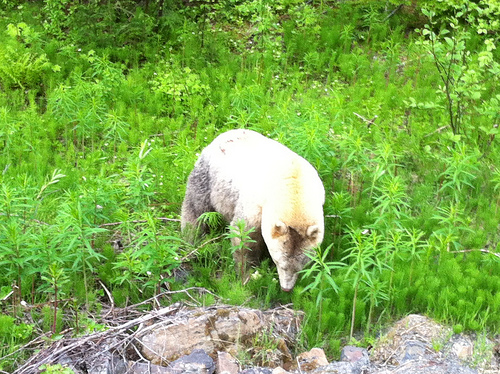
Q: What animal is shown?
A: Bear.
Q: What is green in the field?
A: Vegetation.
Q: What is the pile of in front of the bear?
A: Rocks.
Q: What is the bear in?
A: Grass.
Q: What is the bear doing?
A: Standing.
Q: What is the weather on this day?
A: Sunny.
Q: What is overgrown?
A: Plants.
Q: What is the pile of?
A: A pile of rocks.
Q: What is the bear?
A: A lightly colored bear.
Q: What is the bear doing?
A: A bear looking for food.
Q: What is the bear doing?
A: A bear foraging for food.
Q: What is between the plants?
A: A bear between plants.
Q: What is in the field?
A: A field of various plants.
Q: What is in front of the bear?
A: Rocks and stones in front of bear.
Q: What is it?
A: A bear.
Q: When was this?
A: Daytime.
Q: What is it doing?
A: Looking for food.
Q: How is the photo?
A: Clear.